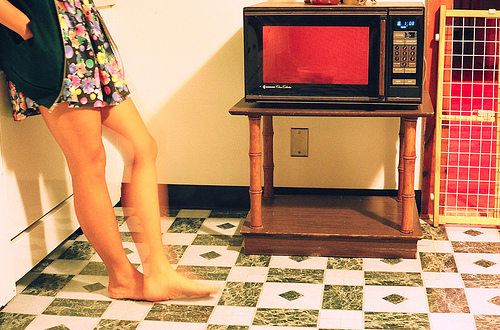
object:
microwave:
[240, 0, 430, 109]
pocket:
[7, 11, 64, 93]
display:
[393, 15, 422, 32]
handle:
[377, 17, 389, 103]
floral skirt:
[0, 0, 120, 113]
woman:
[0, 0, 225, 303]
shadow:
[0, 73, 79, 268]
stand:
[227, 95, 438, 260]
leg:
[39, 100, 146, 303]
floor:
[0, 197, 500, 329]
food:
[296, 66, 337, 84]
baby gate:
[430, 2, 500, 228]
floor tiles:
[427, 311, 477, 330]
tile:
[361, 284, 431, 314]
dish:
[296, 65, 341, 83]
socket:
[290, 127, 309, 158]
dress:
[2, 0, 132, 121]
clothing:
[1, 0, 133, 123]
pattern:
[67, 17, 98, 94]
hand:
[25, 18, 55, 54]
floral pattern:
[5, 0, 135, 124]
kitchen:
[0, 0, 500, 330]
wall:
[117, 0, 427, 193]